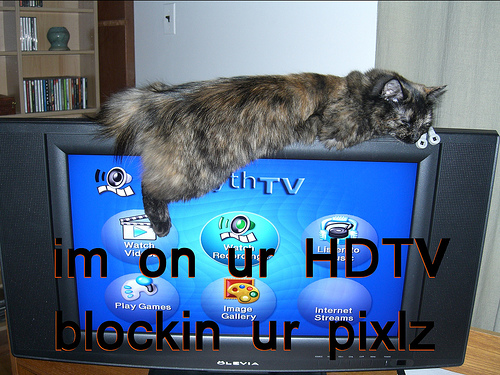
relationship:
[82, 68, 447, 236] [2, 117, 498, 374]
cat laying on television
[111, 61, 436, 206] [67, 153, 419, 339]
cat laying on screen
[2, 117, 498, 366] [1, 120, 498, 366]
television has speakers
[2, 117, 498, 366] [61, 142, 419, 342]
television has screen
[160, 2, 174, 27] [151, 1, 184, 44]
switch on wall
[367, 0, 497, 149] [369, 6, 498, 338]
curtain over window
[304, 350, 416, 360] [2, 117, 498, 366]
buttons on television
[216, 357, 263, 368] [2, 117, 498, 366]
brand on television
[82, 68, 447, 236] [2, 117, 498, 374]
cat on television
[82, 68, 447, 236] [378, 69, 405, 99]
cat has ear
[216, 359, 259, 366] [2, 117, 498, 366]
brand on television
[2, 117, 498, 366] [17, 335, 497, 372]
television on floor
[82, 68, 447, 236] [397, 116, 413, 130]
cat has eye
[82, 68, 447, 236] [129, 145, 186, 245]
cat has leg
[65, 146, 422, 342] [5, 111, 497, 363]
digital display on screen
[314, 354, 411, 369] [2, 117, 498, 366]
control panel on television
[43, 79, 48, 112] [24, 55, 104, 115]
dvds on shelf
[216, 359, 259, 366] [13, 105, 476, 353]
brand on tv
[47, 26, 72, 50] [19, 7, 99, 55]
vase on shelf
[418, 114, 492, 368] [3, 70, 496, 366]
speaker built into television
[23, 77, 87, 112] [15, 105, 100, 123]
dvds are on shelf